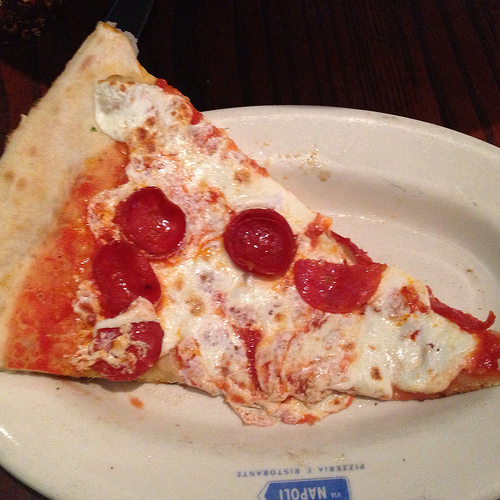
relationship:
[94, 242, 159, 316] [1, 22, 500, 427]
pepperoni on pizza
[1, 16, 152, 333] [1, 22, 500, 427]
crust of pizza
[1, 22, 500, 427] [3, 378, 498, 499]
pizza on plate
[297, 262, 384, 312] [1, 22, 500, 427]
pepperoni on pizza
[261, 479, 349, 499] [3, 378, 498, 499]
logo on plate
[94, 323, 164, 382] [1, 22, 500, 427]
pepperoni on pizza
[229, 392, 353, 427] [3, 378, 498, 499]
cheese on plate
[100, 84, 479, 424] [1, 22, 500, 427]
cheese on pizza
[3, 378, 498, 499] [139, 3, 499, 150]
plate on table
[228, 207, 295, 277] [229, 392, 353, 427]
pepperoni and cheese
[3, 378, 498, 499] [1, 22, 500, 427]
plate under pizza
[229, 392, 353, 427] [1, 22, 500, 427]
cheese falling off pizza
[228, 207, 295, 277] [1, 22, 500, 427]
pepperoni on pizza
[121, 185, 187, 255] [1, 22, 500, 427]
pepperoni on pizza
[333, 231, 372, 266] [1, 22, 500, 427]
pepperoni on pizza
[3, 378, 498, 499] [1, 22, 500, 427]
plate holding pizza